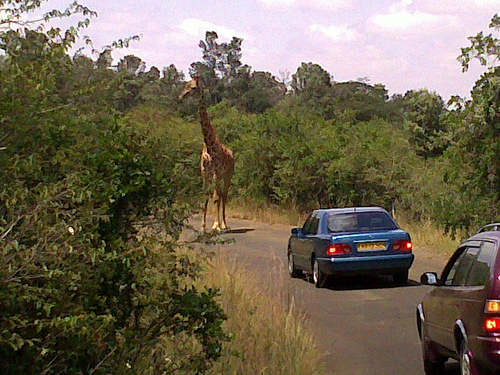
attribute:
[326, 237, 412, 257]
tail lights — red, illuminated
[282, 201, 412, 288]
car — blue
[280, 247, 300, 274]
tire — black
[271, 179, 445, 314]
car — blue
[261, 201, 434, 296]
car — blue, 4-door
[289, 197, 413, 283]
car — blue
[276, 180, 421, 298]
car — blue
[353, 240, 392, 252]
license — yellow, rectangular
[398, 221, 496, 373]
car — red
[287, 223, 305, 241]
mirror — rearview mirror